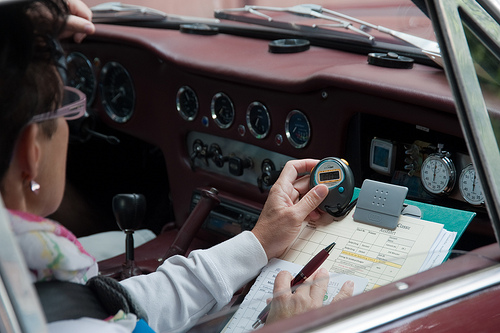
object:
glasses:
[29, 84, 88, 121]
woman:
[1, 13, 354, 331]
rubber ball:
[108, 191, 146, 233]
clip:
[350, 176, 407, 231]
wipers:
[176, 12, 431, 57]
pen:
[252, 244, 335, 325]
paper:
[390, 236, 426, 273]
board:
[439, 205, 478, 237]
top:
[109, 180, 148, 228]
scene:
[1, 1, 498, 331]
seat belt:
[31, 272, 151, 322]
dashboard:
[117, 22, 467, 169]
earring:
[21, 174, 44, 205]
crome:
[426, 40, 498, 94]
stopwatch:
[305, 155, 358, 217]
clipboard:
[284, 178, 479, 269]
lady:
[3, 11, 341, 326]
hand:
[254, 156, 336, 263]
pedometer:
[100, 59, 140, 124]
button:
[337, 183, 345, 192]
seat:
[0, 187, 138, 331]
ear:
[25, 124, 45, 193]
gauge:
[247, 104, 272, 138]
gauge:
[282, 107, 310, 145]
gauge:
[209, 89, 240, 131]